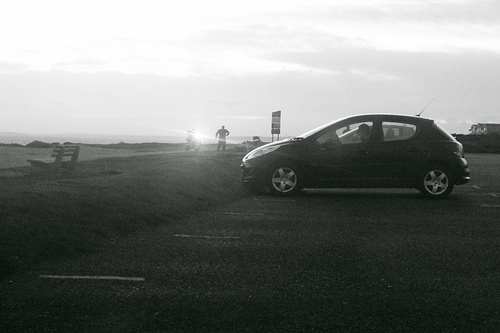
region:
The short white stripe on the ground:
[42, 272, 146, 284]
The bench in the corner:
[31, 142, 82, 173]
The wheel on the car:
[418, 169, 453, 197]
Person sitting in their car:
[345, 121, 367, 143]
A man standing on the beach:
[211, 123, 231, 153]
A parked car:
[241, 113, 472, 195]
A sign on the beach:
[272, 105, 284, 143]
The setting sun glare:
[182, 125, 206, 149]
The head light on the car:
[242, 149, 284, 160]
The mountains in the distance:
[10, 131, 112, 143]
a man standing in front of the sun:
[210, 122, 230, 150]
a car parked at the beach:
[243, 111, 475, 213]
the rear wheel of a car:
[416, 156, 456, 196]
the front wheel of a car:
[268, 163, 302, 197]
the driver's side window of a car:
[327, 123, 373, 143]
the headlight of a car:
[243, 137, 273, 159]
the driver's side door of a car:
[323, 115, 375, 182]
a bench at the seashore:
[20, 137, 92, 182]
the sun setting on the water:
[187, 121, 212, 140]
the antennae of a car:
[411, 93, 438, 118]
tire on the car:
[264, 165, 296, 197]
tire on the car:
[419, 170, 445, 199]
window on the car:
[332, 114, 372, 146]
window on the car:
[385, 118, 406, 140]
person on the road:
[213, 124, 231, 149]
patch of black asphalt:
[213, 260, 232, 279]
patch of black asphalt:
[364, 293, 392, 323]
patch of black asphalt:
[407, 232, 436, 261]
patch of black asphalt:
[254, 291, 286, 323]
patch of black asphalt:
[318, 231, 354, 272]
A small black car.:
[240, 115, 471, 200]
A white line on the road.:
[36, 272, 147, 284]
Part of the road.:
[264, 273, 337, 307]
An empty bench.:
[27, 145, 81, 171]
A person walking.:
[213, 126, 230, 150]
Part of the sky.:
[62, 84, 148, 121]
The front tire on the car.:
[270, 163, 297, 193]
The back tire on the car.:
[421, 166, 452, 198]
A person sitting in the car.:
[356, 123, 372, 141]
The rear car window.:
[379, 118, 416, 142]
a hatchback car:
[225, 105, 474, 207]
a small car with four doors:
[231, 111, 474, 208]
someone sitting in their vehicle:
[350, 119, 381, 150]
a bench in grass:
[21, 132, 83, 182]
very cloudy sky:
[8, 24, 496, 130]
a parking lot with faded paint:
[77, 129, 496, 331]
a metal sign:
[265, 106, 283, 138]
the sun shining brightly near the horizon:
[185, 122, 206, 146]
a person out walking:
[210, 122, 236, 157]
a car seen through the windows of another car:
[326, 122, 424, 152]